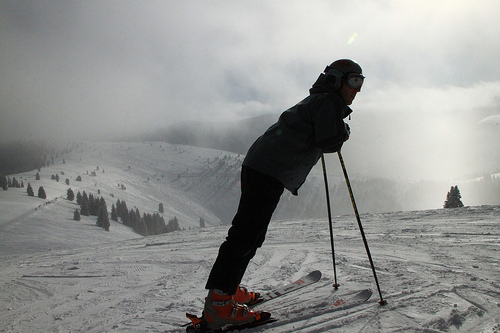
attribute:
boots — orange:
[201, 287, 271, 330]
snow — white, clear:
[8, 139, 499, 329]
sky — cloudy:
[3, 0, 499, 141]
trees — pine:
[3, 176, 205, 232]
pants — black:
[204, 164, 283, 291]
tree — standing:
[444, 185, 466, 208]